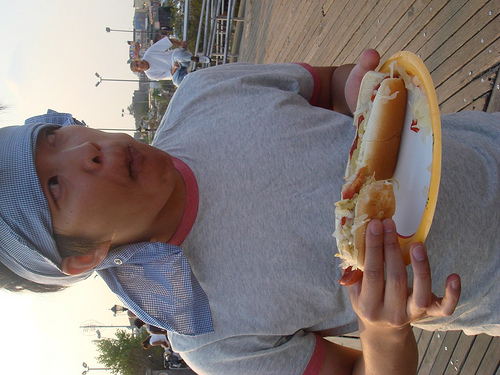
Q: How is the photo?
A: Clear.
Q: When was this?
A: Daytime.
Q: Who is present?
A: A man.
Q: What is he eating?
A: A hotdog.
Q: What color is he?
A: White.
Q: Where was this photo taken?
A: On a boardwalk.